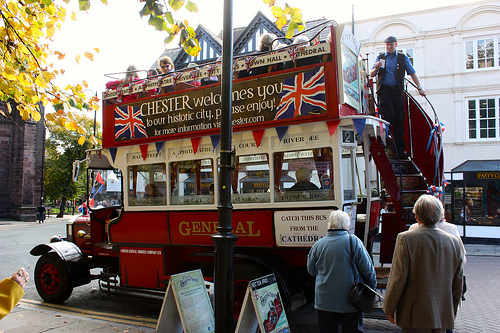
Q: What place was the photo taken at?
A: It was taken at the road.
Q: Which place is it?
A: It is a road.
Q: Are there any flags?
A: Yes, there is a flag.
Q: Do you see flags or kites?
A: Yes, there is a flag.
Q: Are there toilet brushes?
A: No, there are no toilet brushes.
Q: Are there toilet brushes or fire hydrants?
A: No, there are no toilet brushes or fire hydrants.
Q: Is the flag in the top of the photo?
A: Yes, the flag is in the top of the image.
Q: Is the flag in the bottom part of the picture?
A: No, the flag is in the top of the image.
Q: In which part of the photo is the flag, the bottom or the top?
A: The flag is in the top of the image.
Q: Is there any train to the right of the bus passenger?
A: No, there is a flag to the right of the passenger.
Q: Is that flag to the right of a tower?
A: No, the flag is to the right of the passenger.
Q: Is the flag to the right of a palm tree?
A: No, the flag is to the right of a passenger.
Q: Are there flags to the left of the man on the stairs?
A: Yes, there is a flag to the left of the man.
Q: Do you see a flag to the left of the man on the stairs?
A: Yes, there is a flag to the left of the man.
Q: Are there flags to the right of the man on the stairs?
A: No, the flag is to the left of the man.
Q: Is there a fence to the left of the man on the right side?
A: No, there is a flag to the left of the man.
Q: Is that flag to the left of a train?
A: No, the flag is to the left of the man.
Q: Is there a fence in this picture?
A: No, there are no fences.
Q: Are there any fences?
A: No, there are no fences.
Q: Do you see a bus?
A: Yes, there is a bus.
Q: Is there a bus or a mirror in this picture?
A: Yes, there is a bus.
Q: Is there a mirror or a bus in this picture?
A: Yes, there is a bus.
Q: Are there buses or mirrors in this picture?
A: Yes, there is a bus.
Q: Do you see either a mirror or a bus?
A: Yes, there is a bus.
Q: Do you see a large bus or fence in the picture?
A: Yes, there is a large bus.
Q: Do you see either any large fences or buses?
A: Yes, there is a large bus.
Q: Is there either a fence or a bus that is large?
A: Yes, the bus is large.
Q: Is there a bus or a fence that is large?
A: Yes, the bus is large.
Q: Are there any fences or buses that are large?
A: Yes, the bus is large.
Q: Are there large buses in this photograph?
A: Yes, there is a large bus.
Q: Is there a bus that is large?
A: Yes, there is a bus that is large.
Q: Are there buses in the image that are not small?
A: Yes, there is a large bus.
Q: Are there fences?
A: No, there are no fences.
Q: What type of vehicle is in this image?
A: The vehicle is a bus.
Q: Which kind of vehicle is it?
A: The vehicle is a bus.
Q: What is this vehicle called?
A: This is a bus.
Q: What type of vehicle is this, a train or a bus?
A: This is a bus.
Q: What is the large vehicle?
A: The vehicle is a bus.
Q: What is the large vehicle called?
A: The vehicle is a bus.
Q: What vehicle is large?
A: The vehicle is a bus.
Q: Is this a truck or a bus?
A: This is a bus.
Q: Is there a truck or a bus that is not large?
A: No, there is a bus but it is large.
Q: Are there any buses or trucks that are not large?
A: No, there is a bus but it is large.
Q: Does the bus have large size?
A: Yes, the bus is large.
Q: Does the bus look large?
A: Yes, the bus is large.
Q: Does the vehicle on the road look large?
A: Yes, the bus is large.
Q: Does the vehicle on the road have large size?
A: Yes, the bus is large.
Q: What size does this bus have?
A: The bus has large size.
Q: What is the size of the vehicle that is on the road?
A: The bus is large.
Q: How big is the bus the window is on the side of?
A: The bus is large.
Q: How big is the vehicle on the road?
A: The bus is large.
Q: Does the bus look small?
A: No, the bus is large.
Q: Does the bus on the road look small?
A: No, the bus is large.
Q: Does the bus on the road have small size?
A: No, the bus is large.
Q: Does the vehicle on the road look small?
A: No, the bus is large.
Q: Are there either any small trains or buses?
A: No, there is a bus but it is large.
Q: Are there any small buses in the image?
A: No, there is a bus but it is large.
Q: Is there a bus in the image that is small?
A: No, there is a bus but it is large.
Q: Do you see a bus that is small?
A: No, there is a bus but it is large.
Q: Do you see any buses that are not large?
A: No, there is a bus but it is large.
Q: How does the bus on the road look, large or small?
A: The bus is large.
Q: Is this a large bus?
A: Yes, this is a large bus.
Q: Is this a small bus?
A: No, this is a large bus.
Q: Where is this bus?
A: The bus is on the road.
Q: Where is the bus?
A: The bus is on the road.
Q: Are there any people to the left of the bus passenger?
A: Yes, there is a person to the left of the passenger.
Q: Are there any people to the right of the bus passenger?
A: No, the person is to the left of the passenger.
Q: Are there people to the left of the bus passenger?
A: Yes, there is a person to the left of the passenger.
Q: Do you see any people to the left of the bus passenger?
A: Yes, there is a person to the left of the passenger.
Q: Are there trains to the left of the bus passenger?
A: No, there is a person to the left of the passenger.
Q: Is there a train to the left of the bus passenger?
A: No, there is a person to the left of the passenger.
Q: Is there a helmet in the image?
A: No, there are no helmets.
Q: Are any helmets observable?
A: No, there are no helmets.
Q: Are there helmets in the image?
A: No, there are no helmets.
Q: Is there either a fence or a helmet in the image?
A: No, there are no helmets or fences.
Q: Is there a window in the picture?
A: Yes, there is a window.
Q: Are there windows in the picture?
A: Yes, there is a window.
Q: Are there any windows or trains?
A: Yes, there is a window.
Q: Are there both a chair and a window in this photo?
A: No, there is a window but no chairs.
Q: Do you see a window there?
A: Yes, there is a window.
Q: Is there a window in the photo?
A: Yes, there is a window.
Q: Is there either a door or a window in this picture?
A: Yes, there is a window.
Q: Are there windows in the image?
A: Yes, there is a window.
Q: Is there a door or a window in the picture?
A: Yes, there is a window.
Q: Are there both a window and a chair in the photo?
A: No, there is a window but no chairs.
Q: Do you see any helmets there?
A: No, there are no helmets.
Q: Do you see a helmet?
A: No, there are no helmets.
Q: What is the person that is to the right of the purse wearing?
A: The person is wearing a jacket.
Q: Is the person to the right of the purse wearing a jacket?
A: Yes, the person is wearing a jacket.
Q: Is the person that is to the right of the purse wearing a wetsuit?
A: No, the person is wearing a jacket.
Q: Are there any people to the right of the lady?
A: Yes, there is a person to the right of the lady.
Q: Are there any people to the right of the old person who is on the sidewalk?
A: Yes, there is a person to the right of the lady.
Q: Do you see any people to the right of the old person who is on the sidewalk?
A: Yes, there is a person to the right of the lady.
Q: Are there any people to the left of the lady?
A: No, the person is to the right of the lady.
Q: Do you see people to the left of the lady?
A: No, the person is to the right of the lady.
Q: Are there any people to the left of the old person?
A: No, the person is to the right of the lady.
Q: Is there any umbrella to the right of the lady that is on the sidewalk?
A: No, there is a person to the right of the lady.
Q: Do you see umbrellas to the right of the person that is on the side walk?
A: No, there is a person to the right of the lady.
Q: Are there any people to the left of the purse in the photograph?
A: No, the person is to the right of the purse.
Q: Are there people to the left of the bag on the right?
A: No, the person is to the right of the purse.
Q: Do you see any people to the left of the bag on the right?
A: No, the person is to the right of the purse.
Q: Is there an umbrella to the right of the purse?
A: No, there is a person to the right of the purse.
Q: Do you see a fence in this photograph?
A: No, there are no fences.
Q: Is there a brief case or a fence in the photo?
A: No, there are no fences or briefcases.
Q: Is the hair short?
A: Yes, the hair is short.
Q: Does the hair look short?
A: Yes, the hair is short.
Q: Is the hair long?
A: No, the hair is short.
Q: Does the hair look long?
A: No, the hair is short.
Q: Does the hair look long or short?
A: The hair is short.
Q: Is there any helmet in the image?
A: No, there are no helmets.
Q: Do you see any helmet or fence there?
A: No, there are no helmets or fences.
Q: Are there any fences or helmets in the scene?
A: No, there are no helmets or fences.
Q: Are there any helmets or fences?
A: No, there are no helmets or fences.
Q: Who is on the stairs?
A: The man is on the stairs.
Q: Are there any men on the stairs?
A: Yes, there is a man on the stairs.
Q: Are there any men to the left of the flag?
A: No, the man is to the right of the flag.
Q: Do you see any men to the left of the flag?
A: No, the man is to the right of the flag.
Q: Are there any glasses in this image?
A: No, there are no glasses.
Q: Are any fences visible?
A: No, there are no fences.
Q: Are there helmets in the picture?
A: No, there are no helmets.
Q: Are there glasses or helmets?
A: No, there are no helmets or glasses.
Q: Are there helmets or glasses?
A: No, there are no helmets or glasses.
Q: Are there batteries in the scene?
A: No, there are no batteries.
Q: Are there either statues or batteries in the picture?
A: No, there are no batteries or statues.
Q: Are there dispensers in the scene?
A: No, there are no dispensers.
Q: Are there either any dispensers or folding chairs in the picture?
A: No, there are no dispensers or folding chairs.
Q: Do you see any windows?
A: Yes, there is a window.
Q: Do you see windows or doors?
A: Yes, there is a window.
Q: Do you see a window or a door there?
A: Yes, there is a window.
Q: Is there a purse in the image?
A: Yes, there is a purse.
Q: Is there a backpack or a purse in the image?
A: Yes, there is a purse.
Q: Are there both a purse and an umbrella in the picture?
A: No, there is a purse but no umbrellas.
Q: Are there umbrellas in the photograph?
A: No, there are no umbrellas.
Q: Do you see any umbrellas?
A: No, there are no umbrellas.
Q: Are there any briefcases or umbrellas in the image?
A: No, there are no umbrellas or briefcases.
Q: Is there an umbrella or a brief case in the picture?
A: No, there are no umbrellas or briefcases.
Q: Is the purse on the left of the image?
A: No, the purse is on the right of the image.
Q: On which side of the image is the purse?
A: The purse is on the right of the image.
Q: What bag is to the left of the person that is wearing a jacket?
A: The bag is a purse.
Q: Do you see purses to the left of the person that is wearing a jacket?
A: Yes, there is a purse to the left of the person.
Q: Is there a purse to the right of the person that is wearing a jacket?
A: No, the purse is to the left of the person.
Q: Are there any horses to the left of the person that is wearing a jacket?
A: No, there is a purse to the left of the person.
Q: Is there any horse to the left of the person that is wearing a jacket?
A: No, there is a purse to the left of the person.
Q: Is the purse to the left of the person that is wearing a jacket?
A: Yes, the purse is to the left of the person.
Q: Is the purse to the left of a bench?
A: No, the purse is to the left of the person.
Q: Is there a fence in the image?
A: No, there are no fences.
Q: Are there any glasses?
A: No, there are no glasses.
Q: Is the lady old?
A: Yes, the lady is old.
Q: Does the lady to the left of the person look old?
A: Yes, the lady is old.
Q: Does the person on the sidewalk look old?
A: Yes, the lady is old.